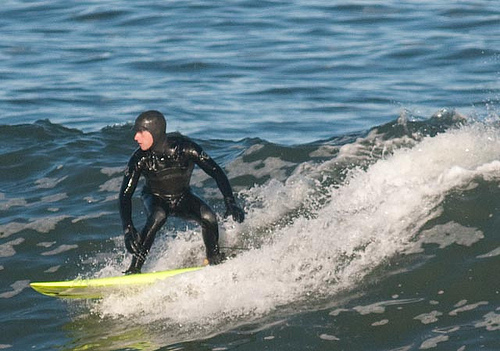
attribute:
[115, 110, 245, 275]
man — surfing, black, outdoors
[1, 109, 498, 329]
wave — huge, crashing, bubbling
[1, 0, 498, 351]
ocean — blue, large, water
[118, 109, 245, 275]
wetsuit — tight, black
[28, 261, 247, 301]
surfboard — yellow, bright, light green, green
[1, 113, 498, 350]
foam — white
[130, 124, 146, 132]
hair — black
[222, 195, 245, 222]
glove — black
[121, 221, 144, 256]
glove — black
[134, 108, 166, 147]
hood — black